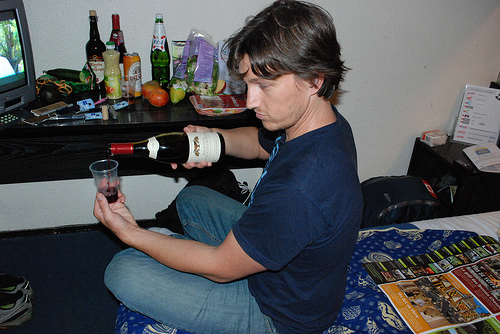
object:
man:
[90, 3, 365, 333]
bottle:
[105, 129, 226, 165]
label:
[184, 130, 222, 166]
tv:
[0, 0, 35, 116]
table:
[0, 84, 319, 184]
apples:
[142, 79, 170, 106]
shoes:
[0, 289, 32, 327]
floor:
[0, 210, 109, 332]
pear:
[169, 83, 186, 104]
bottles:
[83, 9, 171, 101]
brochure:
[460, 141, 500, 170]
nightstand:
[407, 134, 499, 211]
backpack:
[354, 174, 445, 225]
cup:
[88, 157, 118, 203]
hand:
[92, 191, 137, 236]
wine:
[97, 150, 120, 203]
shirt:
[230, 116, 364, 293]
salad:
[174, 39, 225, 94]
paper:
[361, 235, 499, 334]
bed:
[115, 211, 500, 333]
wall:
[1, 0, 499, 215]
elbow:
[168, 237, 249, 283]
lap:
[165, 186, 260, 334]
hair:
[222, 0, 350, 100]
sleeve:
[232, 175, 326, 270]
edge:
[232, 218, 283, 272]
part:
[399, 236, 401, 239]